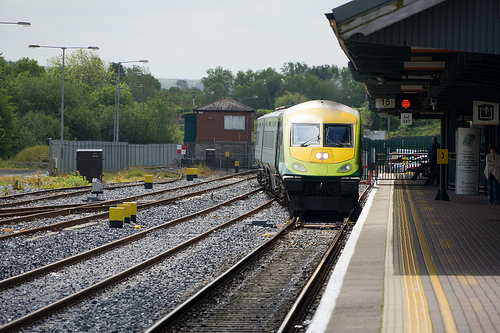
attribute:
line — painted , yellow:
[394, 169, 429, 331]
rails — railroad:
[4, 174, 370, 329]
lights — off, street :
[9, 19, 181, 70]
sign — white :
[374, 96, 397, 108]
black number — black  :
[381, 97, 391, 106]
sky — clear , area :
[159, 12, 295, 52]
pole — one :
[58, 43, 69, 136]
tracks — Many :
[2, 182, 306, 324]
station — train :
[325, 1, 499, 192]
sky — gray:
[0, 1, 355, 78]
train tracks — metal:
[136, 225, 318, 307]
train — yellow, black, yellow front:
[251, 98, 361, 216]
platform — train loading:
[317, 158, 496, 330]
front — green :
[282, 97, 362, 182]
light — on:
[400, 98, 410, 109]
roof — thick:
[319, 7, 404, 69]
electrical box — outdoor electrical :
[73, 146, 105, 185]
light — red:
[388, 88, 425, 128]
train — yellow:
[295, 105, 385, 210]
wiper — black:
[299, 133, 319, 149]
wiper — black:
[334, 128, 350, 144]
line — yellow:
[399, 170, 462, 331]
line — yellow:
[394, 179, 434, 331]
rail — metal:
[140, 208, 306, 331]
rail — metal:
[0, 194, 271, 331]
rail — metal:
[0, 186, 262, 290]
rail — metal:
[0, 173, 257, 246]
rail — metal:
[0, 172, 247, 227]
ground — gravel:
[2, 165, 370, 330]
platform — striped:
[306, 165, 498, 330]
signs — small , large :
[400, 116, 413, 130]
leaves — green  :
[99, 67, 109, 85]